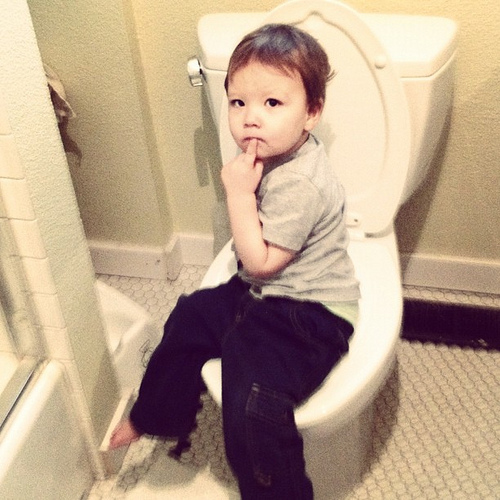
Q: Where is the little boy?
A: On toilet seat.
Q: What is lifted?
A: The seat.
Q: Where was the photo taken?
A: Bathroom.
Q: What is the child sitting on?
A: Toilet.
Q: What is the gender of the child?
A: Male.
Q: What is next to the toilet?
A: Shower.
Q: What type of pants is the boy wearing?
A: Jeans.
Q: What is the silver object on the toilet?
A: Lever.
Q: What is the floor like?
A: Tiled.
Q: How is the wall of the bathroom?
A: Textured.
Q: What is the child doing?
A: Sitting.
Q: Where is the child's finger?
A: Mouth.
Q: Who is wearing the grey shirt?
A: A boy.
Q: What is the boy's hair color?
A: Brown.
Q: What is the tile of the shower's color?
A: White.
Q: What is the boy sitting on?
A: A toilet.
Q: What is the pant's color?
A: Blue.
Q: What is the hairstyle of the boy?
A: Short.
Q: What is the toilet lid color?
A: White.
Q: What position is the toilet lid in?
A: Up.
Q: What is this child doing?
A: Sitting on toilet.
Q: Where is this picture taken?
A: In bathroom.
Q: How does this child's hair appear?
A: Straight.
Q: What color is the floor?
A: White.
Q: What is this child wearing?
A: Jeans.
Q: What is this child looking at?
A: Camera.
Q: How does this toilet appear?
A: Open.